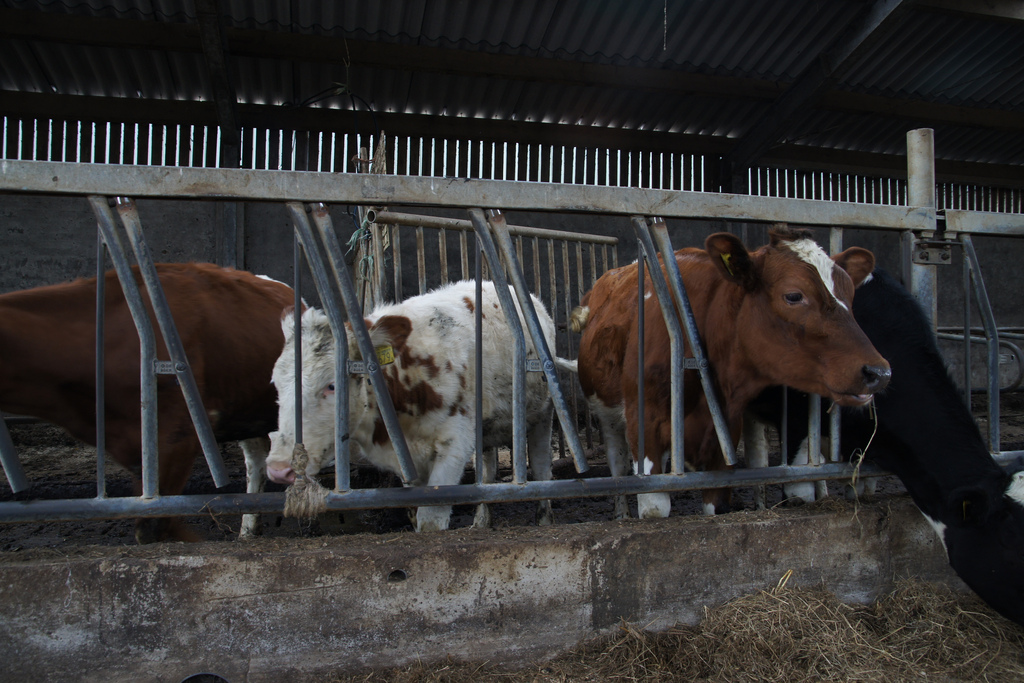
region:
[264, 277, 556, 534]
A mostly white cow with brown spots.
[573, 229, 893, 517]
Largest brown cow with white strip on its head.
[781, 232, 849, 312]
White strip on a brown cow head.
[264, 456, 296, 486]
Pink cow nose on a mostly white cow.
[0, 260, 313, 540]
Brown cow with no visible head.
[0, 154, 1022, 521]
Long metal piece of fence with some cow heads coming through.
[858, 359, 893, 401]
A black nose on a brown and white head cow.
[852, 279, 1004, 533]
A long black cow neck.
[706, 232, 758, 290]
A cows right brown ear.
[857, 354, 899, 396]
Cow has black nose.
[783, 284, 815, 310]
Cow has dark eye.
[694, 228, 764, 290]
Cow has brown ear.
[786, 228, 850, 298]
Cow has white marking on face.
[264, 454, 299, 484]
Cow has pink nose.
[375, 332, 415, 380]
Yellow tag on cow's ear.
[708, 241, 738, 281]
Yellow tag on cow's ear.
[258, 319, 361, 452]
Cow has white face.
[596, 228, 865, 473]
Cow is mostly brown in color.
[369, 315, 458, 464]
Brown markings on white cow.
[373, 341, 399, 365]
yellow tag in cow ear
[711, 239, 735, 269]
yellow tag in cow ear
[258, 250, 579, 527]
Cow in the pin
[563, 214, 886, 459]
Cow in the pin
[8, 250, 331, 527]
Cow in the pin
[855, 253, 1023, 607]
Cow in the pin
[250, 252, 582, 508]
Cow is brown and white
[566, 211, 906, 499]
Cow is brown and white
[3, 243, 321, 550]
Cow is brown and white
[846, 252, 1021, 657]
Cow is black and white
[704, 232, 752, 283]
cow has an ear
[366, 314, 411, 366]
cow has an ear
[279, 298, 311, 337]
cow has an ear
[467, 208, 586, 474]
pole is strong and metal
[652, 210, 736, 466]
pole is strong and metal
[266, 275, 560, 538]
the large brown and white cow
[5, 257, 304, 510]
the large brown and white cow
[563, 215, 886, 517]
the large brown and white cow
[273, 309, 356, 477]
the head of the cow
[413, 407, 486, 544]
the leg of the cow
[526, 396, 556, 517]
the leg of the cow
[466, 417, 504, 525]
the leg of the cow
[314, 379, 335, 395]
the eye of the cow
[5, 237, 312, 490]
The cow to the far left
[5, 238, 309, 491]
A cow to the far left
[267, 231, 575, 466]
The cow in the middle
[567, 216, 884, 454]
A cow to the right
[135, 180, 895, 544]
these are cattle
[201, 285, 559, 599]
this is a cow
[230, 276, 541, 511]
the cow is white and brown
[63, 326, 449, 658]
the wall is stone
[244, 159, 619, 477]
the railing is metal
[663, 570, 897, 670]
the hay is dark gray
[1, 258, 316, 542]
brown cow next to white cow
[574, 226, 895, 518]
brown cow next to white cow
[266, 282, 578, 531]
white cow next to brown cow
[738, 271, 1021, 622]
black cow next to brown cow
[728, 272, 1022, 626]
black cow grazing on hay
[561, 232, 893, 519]
brown cow grazing on hay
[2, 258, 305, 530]
cow standing behind fence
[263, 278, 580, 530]
cow standing behind fence